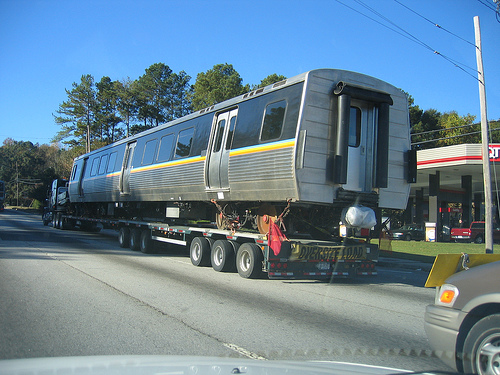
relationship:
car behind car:
[417, 260, 499, 373] [42, 68, 417, 279]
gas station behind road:
[384, 139, 499, 242] [0, 208, 455, 374]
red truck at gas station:
[448, 218, 498, 244] [384, 143, 500, 242]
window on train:
[226, 101, 337, 158] [94, 41, 414, 271]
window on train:
[323, 92, 369, 157] [63, 63, 376, 264]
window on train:
[256, 102, 296, 159] [38, 71, 419, 281]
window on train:
[227, 112, 245, 161] [151, 127, 428, 153]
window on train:
[91, 155, 100, 177] [71, 139, 249, 223]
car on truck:
[32, 58, 430, 286] [27, 172, 67, 212]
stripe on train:
[137, 153, 220, 179] [64, 73, 414, 233]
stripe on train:
[228, 139, 303, 160] [64, 73, 414, 233]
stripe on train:
[419, 153, 482, 172] [64, 73, 414, 233]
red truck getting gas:
[450, 220, 499, 244] [435, 195, 469, 244]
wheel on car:
[191, 221, 214, 279] [42, 68, 417, 279]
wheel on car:
[214, 231, 246, 294] [42, 68, 417, 279]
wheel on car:
[231, 221, 260, 292] [42, 68, 417, 279]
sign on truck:
[291, 236, 387, 268] [35, 61, 453, 311]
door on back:
[328, 81, 395, 207] [285, 57, 334, 191]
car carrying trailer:
[42, 68, 417, 279] [67, 67, 419, 278]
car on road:
[42, 68, 417, 279] [0, 208, 455, 374]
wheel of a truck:
[184, 228, 212, 268] [19, 185, 340, 296]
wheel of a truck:
[188, 234, 221, 273] [29, 181, 316, 286]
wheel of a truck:
[216, 236, 318, 280] [101, 153, 442, 347]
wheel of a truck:
[55, 214, 70, 231] [41, 135, 79, 224]